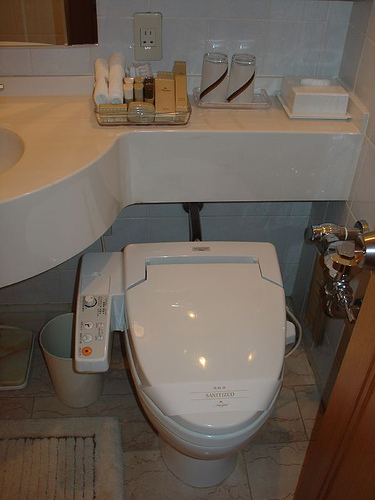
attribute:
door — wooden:
[64, 1, 100, 41]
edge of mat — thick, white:
[1, 415, 123, 498]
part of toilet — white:
[73, 237, 306, 486]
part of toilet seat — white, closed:
[127, 262, 286, 435]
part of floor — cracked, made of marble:
[1, 297, 322, 499]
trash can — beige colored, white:
[39, 312, 103, 408]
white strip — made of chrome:
[73, 253, 123, 374]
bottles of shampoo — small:
[123, 73, 135, 103]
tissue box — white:
[282, 77, 348, 116]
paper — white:
[141, 380, 279, 420]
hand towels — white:
[94, 57, 125, 104]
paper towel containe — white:
[92, 80, 193, 127]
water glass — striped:
[202, 34, 227, 104]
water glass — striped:
[228, 34, 257, 107]